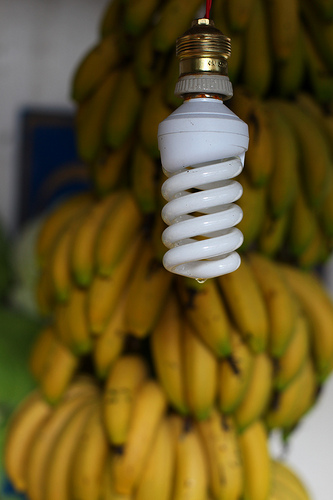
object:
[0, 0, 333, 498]
bananas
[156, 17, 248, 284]
light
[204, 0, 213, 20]
red wire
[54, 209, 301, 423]
bananas bulb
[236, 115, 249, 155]
ground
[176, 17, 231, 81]
socket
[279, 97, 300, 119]
ground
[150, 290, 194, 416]
banana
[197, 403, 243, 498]
banana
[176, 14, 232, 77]
gold metal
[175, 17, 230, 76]
light socket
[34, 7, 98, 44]
wall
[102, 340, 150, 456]
banana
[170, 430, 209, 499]
banana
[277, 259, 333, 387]
banana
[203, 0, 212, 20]
wire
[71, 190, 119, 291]
banana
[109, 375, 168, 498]
banana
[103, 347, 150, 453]
banana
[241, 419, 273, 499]
banana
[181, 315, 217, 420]
banana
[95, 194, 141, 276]
banana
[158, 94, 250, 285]
bulb